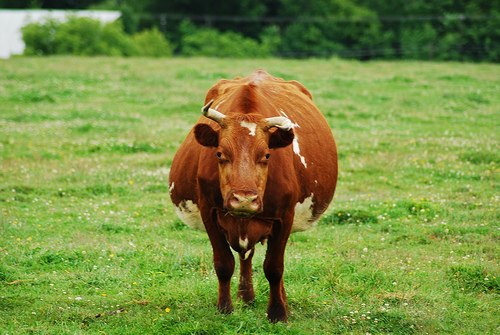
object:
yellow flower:
[419, 195, 431, 201]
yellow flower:
[474, 200, 483, 209]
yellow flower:
[130, 178, 141, 185]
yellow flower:
[108, 250, 117, 259]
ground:
[0, 55, 500, 334]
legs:
[203, 221, 237, 312]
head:
[192, 96, 297, 220]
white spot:
[294, 191, 323, 232]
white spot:
[174, 197, 207, 233]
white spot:
[238, 237, 256, 249]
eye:
[216, 148, 231, 168]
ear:
[266, 125, 297, 150]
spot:
[237, 118, 259, 139]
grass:
[0, 54, 500, 334]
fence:
[0, 0, 500, 58]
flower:
[129, 279, 140, 288]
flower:
[334, 208, 348, 219]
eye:
[258, 150, 273, 163]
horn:
[200, 96, 232, 129]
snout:
[219, 190, 268, 220]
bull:
[168, 66, 339, 324]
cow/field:
[168, 69, 337, 325]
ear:
[192, 122, 221, 151]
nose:
[227, 192, 258, 207]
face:
[215, 120, 271, 213]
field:
[0, 59, 500, 334]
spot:
[290, 134, 310, 171]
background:
[0, 0, 500, 334]